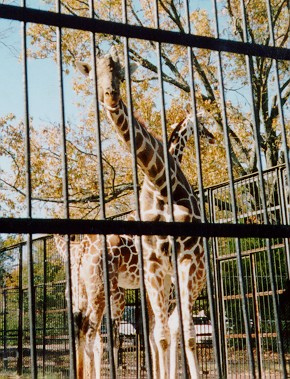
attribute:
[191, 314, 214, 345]
car — White 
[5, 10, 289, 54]
crossbar — Black 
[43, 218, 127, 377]
giraffe — rear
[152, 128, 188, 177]
neck — white 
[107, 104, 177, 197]
neck — Brown 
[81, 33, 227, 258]
giraffe — long, orange, white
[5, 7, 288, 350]
fence — metal , tall 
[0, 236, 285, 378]
fence — long, black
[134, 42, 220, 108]
branches — brown 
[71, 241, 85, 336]
giraffe tail — White , Brown 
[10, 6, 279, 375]
fence — tall, metal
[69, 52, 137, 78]
ears — giraffe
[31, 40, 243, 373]
giraffe — spotted, orange, brown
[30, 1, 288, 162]
tree — brown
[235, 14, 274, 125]
branch — long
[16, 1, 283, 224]
leafy tree — tall 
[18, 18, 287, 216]
leaves — yellow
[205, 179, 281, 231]
tree trunk — brown 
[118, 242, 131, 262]
spots — brown 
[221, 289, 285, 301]
rail — metal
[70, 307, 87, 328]
hair — black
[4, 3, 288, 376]
enclosure — metal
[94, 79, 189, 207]
neck — long